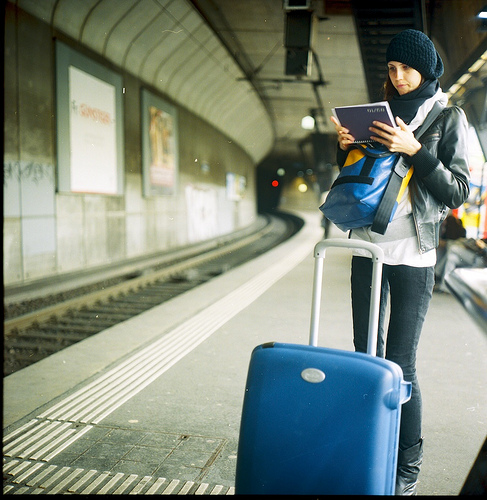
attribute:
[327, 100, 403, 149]
notebook — black, purple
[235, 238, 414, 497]
travel case — blue, plastic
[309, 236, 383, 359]
travel case handle — white, aluminum, grey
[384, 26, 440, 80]
hat — black, knit, wool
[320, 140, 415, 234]
bag — blue, yellow, black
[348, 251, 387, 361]
leg — skinny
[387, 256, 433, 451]
leg — skinny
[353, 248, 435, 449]
pants — dark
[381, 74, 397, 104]
hair — brown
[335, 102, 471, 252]
jacket — black, leather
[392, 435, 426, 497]
boot — leather, black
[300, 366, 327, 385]
label — silver, small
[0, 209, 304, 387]
train tracks — empty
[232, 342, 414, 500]
suitcase — blue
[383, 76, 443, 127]
scarf — black